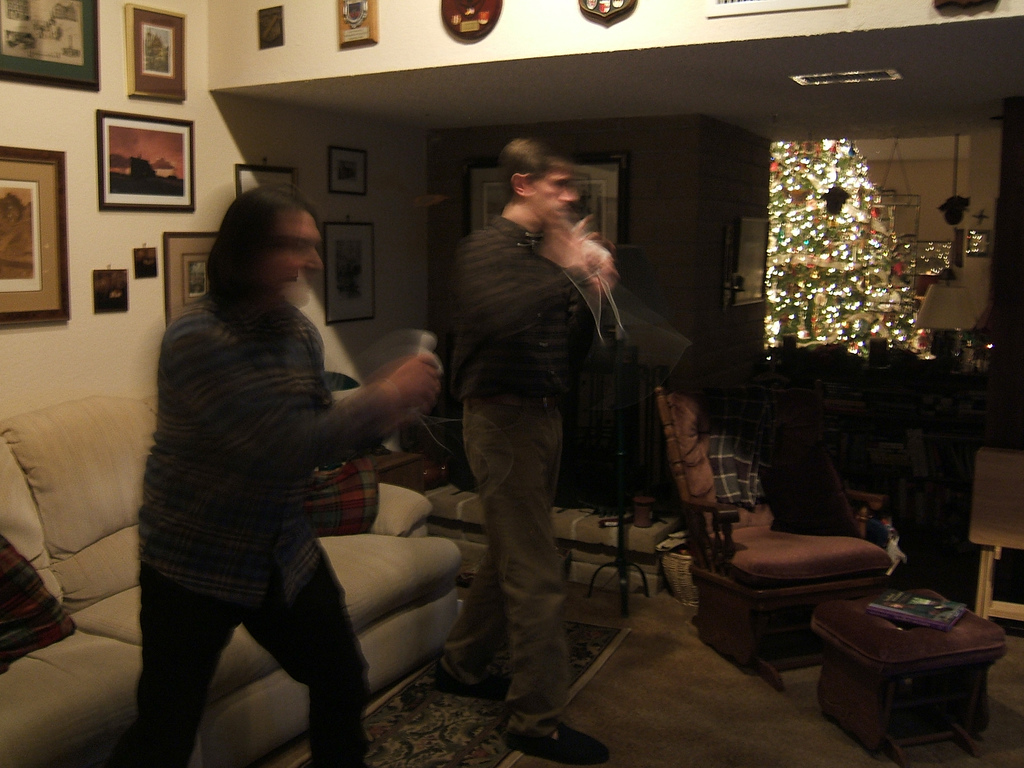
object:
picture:
[9, 142, 83, 339]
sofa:
[13, 358, 478, 763]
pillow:
[2, 523, 90, 679]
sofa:
[2, 293, 467, 751]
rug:
[575, 620, 794, 765]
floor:
[433, 629, 920, 766]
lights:
[769, 136, 944, 359]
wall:
[728, 58, 983, 404]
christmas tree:
[769, 125, 955, 370]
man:
[432, 126, 678, 732]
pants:
[443, 375, 632, 703]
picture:
[91, 104, 200, 217]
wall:
[2, 1, 437, 428]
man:
[118, 180, 443, 762]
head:
[198, 178, 329, 336]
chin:
[266, 275, 320, 314]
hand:
[370, 350, 449, 428]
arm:
[164, 338, 389, 481]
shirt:
[132, 297, 398, 609]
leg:
[118, 565, 242, 763]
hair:
[195, 182, 316, 347]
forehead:
[274, 201, 329, 247]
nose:
[299, 243, 327, 276]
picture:
[3, 121, 83, 357]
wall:
[76, 210, 115, 237]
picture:
[17, 22, 204, 133]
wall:
[36, 98, 91, 151]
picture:
[137, 223, 192, 316]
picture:
[307, 124, 370, 204]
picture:
[323, 206, 408, 330]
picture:
[210, 145, 316, 198]